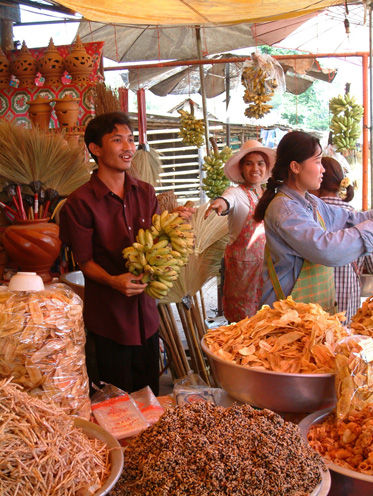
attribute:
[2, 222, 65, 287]
pot — clay, large, orange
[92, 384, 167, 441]
bag — plastic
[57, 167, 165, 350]
shirt — maroon, brown, buttoned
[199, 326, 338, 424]
bowl — metal, big, steel, silver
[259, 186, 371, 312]
shirt — blue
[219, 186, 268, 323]
apron — red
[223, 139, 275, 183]
hat — white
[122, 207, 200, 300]
bananas — ripe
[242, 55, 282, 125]
bananas — green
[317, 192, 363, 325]
shirt — plaid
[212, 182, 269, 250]
shirt — white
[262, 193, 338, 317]
apron — green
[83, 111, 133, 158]
hair — brown, dark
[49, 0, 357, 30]
canopy — yellow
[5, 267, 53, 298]
bowl — white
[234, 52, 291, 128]
bag — clear